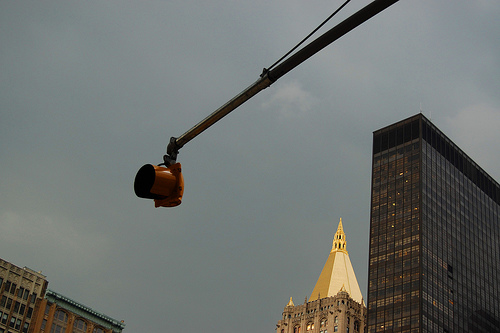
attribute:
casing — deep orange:
[133, 163, 186, 209]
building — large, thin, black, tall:
[367, 113, 500, 332]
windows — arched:
[367, 148, 419, 331]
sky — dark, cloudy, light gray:
[1, 1, 500, 111]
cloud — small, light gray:
[270, 81, 324, 118]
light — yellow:
[132, 161, 186, 208]